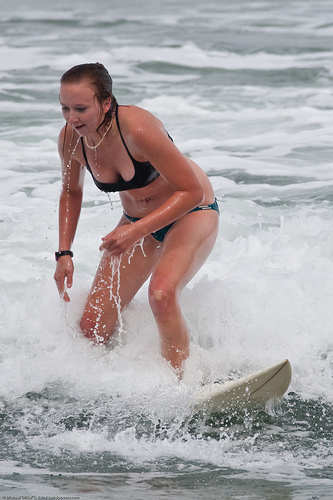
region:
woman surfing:
[45, 61, 241, 432]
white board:
[197, 351, 292, 426]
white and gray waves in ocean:
[197, 23, 234, 63]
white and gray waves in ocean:
[266, 292, 296, 341]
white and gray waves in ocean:
[80, 430, 116, 458]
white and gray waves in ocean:
[214, 81, 274, 118]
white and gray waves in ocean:
[134, 35, 188, 67]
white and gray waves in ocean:
[22, 17, 50, 28]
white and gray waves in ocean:
[9, 84, 38, 137]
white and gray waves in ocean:
[11, 280, 32, 327]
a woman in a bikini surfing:
[27, 56, 297, 413]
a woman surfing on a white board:
[44, 58, 303, 410]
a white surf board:
[122, 357, 299, 442]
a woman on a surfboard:
[36, 53, 303, 407]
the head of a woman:
[54, 58, 115, 143]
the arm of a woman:
[51, 155, 84, 301]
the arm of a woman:
[133, 120, 205, 236]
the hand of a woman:
[94, 223, 137, 262]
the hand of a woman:
[46, 257, 79, 304]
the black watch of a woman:
[51, 249, 77, 260]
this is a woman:
[38, 63, 215, 348]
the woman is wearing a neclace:
[87, 127, 106, 148]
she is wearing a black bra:
[133, 157, 148, 188]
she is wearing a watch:
[52, 247, 69, 259]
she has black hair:
[98, 66, 111, 107]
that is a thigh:
[161, 211, 198, 280]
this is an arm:
[56, 153, 88, 250]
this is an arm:
[133, 204, 196, 225]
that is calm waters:
[236, 218, 259, 307]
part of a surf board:
[244, 366, 292, 405]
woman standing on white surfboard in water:
[33, 58, 303, 436]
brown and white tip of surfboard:
[175, 337, 308, 432]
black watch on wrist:
[47, 241, 77, 267]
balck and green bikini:
[58, 113, 244, 246]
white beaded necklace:
[76, 114, 133, 150]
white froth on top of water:
[149, 39, 330, 79]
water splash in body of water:
[33, 370, 212, 452]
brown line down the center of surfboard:
[245, 354, 287, 403]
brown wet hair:
[45, 52, 125, 118]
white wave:
[1, 248, 332, 405]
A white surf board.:
[192, 357, 295, 418]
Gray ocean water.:
[0, 0, 332, 175]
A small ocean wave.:
[0, 208, 332, 498]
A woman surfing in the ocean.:
[52, 61, 220, 383]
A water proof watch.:
[53, 248, 74, 259]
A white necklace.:
[82, 109, 117, 148]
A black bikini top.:
[79, 107, 160, 192]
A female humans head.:
[57, 61, 117, 136]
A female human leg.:
[148, 205, 219, 380]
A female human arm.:
[97, 114, 206, 254]